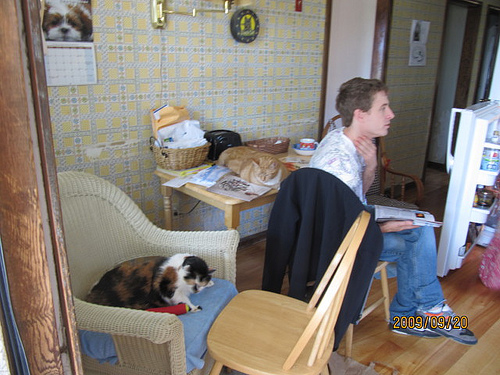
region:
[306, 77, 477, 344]
A man with short brown hair sitting in jeans.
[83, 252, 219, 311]
A calico cat that is asleep.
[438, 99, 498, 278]
An open white fridge door.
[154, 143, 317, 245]
A brown table with a cat on it.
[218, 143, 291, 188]
An orange and white cat on a table.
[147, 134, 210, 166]
A wicker basket full of papers.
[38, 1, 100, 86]
A dog calender on the wall.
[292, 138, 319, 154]
A coffee mug in a saucer on the table.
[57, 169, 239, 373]
A white wicker chair with a calico cat in it.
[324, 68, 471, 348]
a person sitting down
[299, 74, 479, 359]
the person is sitting on a chair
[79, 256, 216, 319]
a cat laying on a chair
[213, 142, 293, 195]
cat laying on the table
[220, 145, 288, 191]
the cat is light tan in color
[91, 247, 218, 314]
the cat is black and brown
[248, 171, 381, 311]
a black jacket on the back of the chair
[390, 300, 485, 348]
sneakers being worn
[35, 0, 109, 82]
an animal calendar on the wall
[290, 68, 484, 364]
man wearing white shirt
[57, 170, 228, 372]
white wicker chair with blue pad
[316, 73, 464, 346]
man wearing blue jeans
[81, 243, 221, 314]
brown, black, and white cat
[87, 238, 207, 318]
cat sitting on chair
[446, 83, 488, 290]
door to fridge open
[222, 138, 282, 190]
cat sitting on table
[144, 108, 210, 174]
wicker basket with papers in it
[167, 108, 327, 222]
small wood table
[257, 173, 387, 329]
jacket hanging on a chair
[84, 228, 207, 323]
cat sitting on a blue pillow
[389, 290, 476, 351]
man wearing blue sneakers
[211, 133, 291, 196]
cat sitting on a table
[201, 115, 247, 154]
toaster on the table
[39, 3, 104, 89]
calendar on the wall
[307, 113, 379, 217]
man wearing a white shirt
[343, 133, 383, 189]
man with his hand on his neck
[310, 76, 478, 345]
Man sitting on a chair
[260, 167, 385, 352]
Coat hanging on the chair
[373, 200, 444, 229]
Book on the man's lap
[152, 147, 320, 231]
Table behind the man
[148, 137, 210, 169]
Basket on the table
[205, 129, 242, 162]
Toaster on the table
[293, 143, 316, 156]
Plate on the table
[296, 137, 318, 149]
Cup on the plate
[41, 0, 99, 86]
Calendar on the wall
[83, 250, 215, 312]
Cat on the chair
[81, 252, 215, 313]
calico cat sleeping on chair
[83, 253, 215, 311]
brown black and white sleeping cat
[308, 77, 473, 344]
man wearing white shirt and blue jeans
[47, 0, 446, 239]
blue white and yellow patterned wallpaper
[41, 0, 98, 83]
wall calendar featuring brown and white dog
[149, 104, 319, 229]
light wooden table holding a lot of clutter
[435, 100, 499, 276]
open white refrigerator door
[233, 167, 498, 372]
light brown hardwood floor with long planks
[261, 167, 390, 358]
dark colored long sleeved jacket hanging on chair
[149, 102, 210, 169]
wicker basket holding yellow folder and papers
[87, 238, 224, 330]
cat sitting on chair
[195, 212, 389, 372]
light brown wooden chair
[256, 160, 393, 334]
black jacket on chair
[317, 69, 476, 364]
man sitting on chair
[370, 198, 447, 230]
open magazine on lap